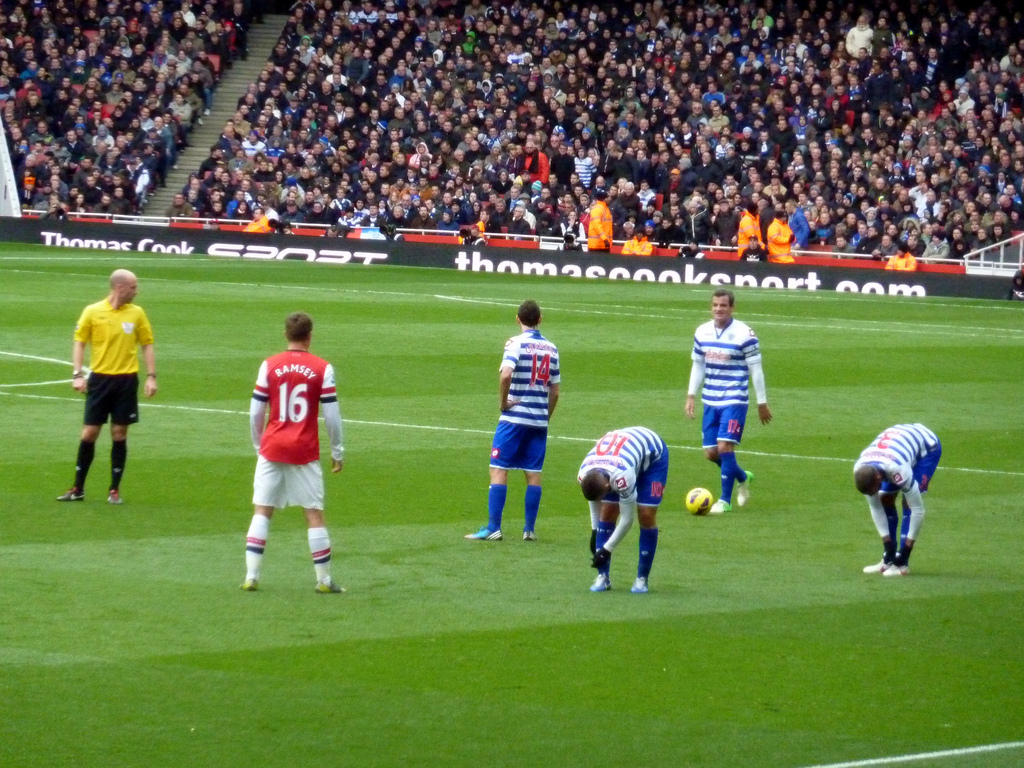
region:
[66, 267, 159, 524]
Referee for the soccer game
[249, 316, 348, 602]
Player wearing red jersey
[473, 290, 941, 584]
Four players wearing red and blue jerseys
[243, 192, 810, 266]
security wearing orange jackets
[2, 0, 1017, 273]
many fans watching the soccer match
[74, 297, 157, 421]
yellow and black referee uniform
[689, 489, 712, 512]
yellow and black soccer ball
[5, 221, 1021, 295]
Multiple signs showing advertisements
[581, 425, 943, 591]
two men bending over tieing their shoes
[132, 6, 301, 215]
Stairway to get into the stands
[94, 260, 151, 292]
Person has bald head.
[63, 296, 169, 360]
Person wearing yellow shirt.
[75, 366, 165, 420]
Person wearing black shorts.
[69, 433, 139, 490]
Person wearing black socks.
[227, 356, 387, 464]
Person wearing red, white and blue jersey.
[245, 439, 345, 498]
Person wearing white shorts.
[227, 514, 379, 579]
Person wearing tall soccer socks.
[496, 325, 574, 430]
Person wearing white and blue striped shirt.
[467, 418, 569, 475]
Person wearing blue shorts.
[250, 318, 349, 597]
person is playing soccer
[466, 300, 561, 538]
person is playing soccer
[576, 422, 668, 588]
person is playing soccer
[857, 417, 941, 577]
person is playing soccer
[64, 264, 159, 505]
person is playing soccer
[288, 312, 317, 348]
person has a head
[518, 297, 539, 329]
person has a head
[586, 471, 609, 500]
person has a head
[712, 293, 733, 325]
person has a head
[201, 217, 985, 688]
Five players on a soccer field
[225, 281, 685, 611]
Players on a soccer field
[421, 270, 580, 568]
Soccer player waiting for free kick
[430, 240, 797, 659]
Three soccer players on a soccer field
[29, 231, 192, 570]
Official on a soccer field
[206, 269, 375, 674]
Soccer player in red "16" jersey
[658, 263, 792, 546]
Soccer player getting ready to kick ball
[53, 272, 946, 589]
Soccer players on the field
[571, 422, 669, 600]
Soccer player bending over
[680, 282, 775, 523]
Player standing next to the soccer ball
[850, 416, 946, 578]
Soccer player tying his shoe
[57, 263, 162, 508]
Man in yellow shirt and black shorts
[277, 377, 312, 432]
The number 16 on the player's jersey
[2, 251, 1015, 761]
Green grass on the soccer field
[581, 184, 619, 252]
Person wearing a yellow jacket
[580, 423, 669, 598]
the soccer player in front is bending over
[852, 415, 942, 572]
a soccer player in back is bending over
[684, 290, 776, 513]
a soccer player is ready to kick the ball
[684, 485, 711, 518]
the soccer ball is yellow and black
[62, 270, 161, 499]
the referee is watching the soccer players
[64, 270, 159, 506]
the referee is bald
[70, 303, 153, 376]
the referee wears a yellow shirt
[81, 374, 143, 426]
the referee wears black shorts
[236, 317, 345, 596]
one soccer player wears a red jersey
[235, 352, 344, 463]
the jersey has the number 16 on it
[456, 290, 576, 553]
player wearing an uniform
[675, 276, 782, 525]
player wearing a blue and white uniform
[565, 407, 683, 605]
player is bend forward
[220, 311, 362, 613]
player is number 16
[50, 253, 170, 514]
referee has yellow top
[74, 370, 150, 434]
the shorts are black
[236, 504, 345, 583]
socks are white with blue and red stripes